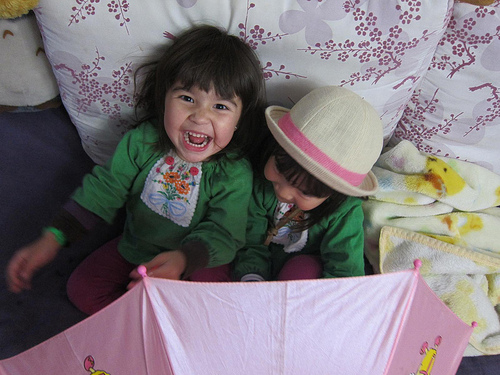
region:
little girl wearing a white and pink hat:
[276, 91, 371, 264]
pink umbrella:
[117, 262, 456, 373]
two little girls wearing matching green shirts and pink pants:
[98, 25, 382, 279]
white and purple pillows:
[271, 3, 486, 79]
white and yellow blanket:
[381, 160, 490, 256]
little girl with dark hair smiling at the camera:
[158, 33, 251, 165]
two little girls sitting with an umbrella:
[134, 36, 383, 359]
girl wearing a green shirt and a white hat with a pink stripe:
[263, 89, 380, 272]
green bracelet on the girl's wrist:
[43, 223, 73, 245]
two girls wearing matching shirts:
[77, 27, 409, 274]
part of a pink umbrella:
[1, 257, 478, 374]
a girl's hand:
[1, 247, 46, 293]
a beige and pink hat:
[268, 85, 388, 202]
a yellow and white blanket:
[375, 141, 499, 359]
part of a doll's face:
[268, 153, 328, 210]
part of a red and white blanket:
[389, 1, 499, 160]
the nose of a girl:
[189, 105, 209, 126]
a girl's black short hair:
[125, 31, 265, 155]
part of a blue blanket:
[0, 106, 84, 234]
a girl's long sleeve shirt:
[41, 122, 257, 270]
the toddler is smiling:
[158, 30, 253, 159]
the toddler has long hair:
[143, 25, 258, 162]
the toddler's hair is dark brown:
[142, 26, 264, 165]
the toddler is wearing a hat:
[269, 65, 392, 198]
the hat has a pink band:
[281, 105, 373, 188]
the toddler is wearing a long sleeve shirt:
[59, 112, 251, 271]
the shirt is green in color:
[69, 118, 249, 270]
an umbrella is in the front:
[4, 259, 486, 374]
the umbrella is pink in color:
[3, 259, 475, 374]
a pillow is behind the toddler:
[33, 3, 438, 192]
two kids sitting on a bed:
[5, 30, 381, 302]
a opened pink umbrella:
[0, 257, 479, 372]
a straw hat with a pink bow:
[266, 85, 384, 201]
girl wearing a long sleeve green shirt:
[68, 118, 250, 278]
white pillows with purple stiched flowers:
[38, 4, 497, 169]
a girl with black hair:
[136, 24, 263, 162]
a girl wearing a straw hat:
[262, 80, 383, 214]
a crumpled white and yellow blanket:
[363, 137, 497, 358]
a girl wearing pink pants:
[68, 233, 231, 316]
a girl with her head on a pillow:
[138, 25, 265, 160]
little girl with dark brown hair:
[146, 23, 267, 186]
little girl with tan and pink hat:
[261, 87, 394, 215]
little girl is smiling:
[173, 124, 215, 155]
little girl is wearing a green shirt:
[241, 199, 372, 303]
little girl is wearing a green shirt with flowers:
[102, 107, 241, 275]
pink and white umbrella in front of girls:
[139, 262, 449, 373]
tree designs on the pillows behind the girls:
[310, 7, 439, 90]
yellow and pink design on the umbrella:
[399, 331, 448, 372]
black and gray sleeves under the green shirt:
[33, 182, 123, 253]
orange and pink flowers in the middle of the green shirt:
[148, 137, 203, 231]